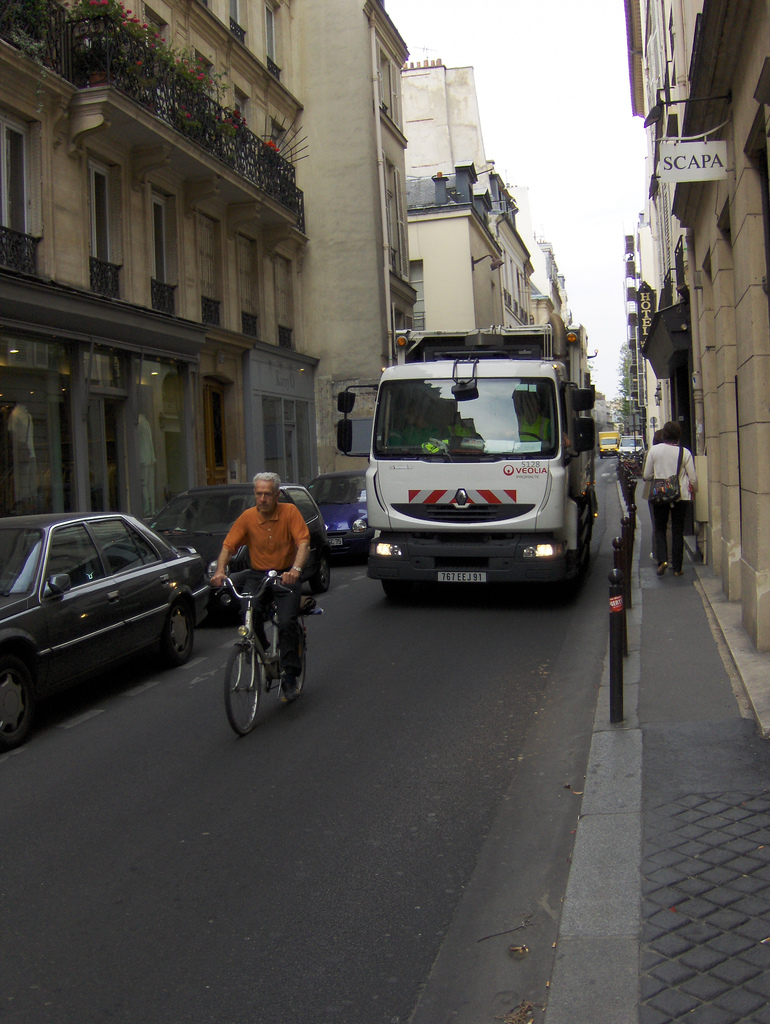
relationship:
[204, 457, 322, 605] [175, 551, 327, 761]
man on a bike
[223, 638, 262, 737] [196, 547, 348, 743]
wheel of bike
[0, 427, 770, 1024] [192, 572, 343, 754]
road next to bike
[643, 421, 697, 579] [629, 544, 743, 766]
woman walking on sidewalk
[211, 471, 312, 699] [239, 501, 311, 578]
man wearing a shirt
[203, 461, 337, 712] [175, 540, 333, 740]
man riding a bike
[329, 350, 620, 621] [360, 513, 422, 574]
truck has headlight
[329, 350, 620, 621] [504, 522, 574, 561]
truck has headlight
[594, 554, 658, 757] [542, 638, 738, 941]
pole on side of street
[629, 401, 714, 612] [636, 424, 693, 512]
woman carrying a bag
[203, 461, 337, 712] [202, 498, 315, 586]
man in a shirt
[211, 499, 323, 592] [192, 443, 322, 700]
shirt on a man